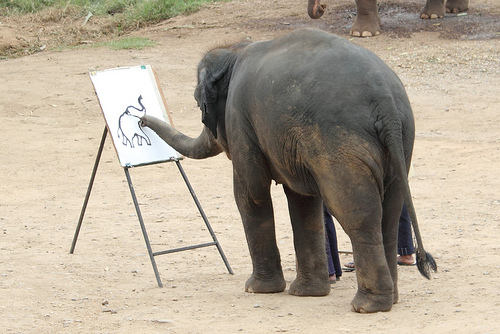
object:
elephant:
[139, 25, 436, 311]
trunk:
[127, 108, 220, 163]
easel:
[68, 62, 236, 290]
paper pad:
[87, 61, 185, 167]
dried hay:
[0, 2, 111, 46]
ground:
[1, 1, 500, 331]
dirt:
[286, 120, 386, 226]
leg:
[319, 151, 395, 296]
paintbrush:
[127, 111, 146, 120]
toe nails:
[248, 284, 258, 291]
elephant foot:
[287, 270, 334, 299]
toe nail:
[345, 29, 353, 37]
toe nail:
[350, 30, 362, 40]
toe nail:
[359, 29, 374, 38]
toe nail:
[371, 29, 382, 35]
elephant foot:
[345, 14, 386, 38]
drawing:
[115, 90, 158, 151]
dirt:
[0, 0, 500, 332]